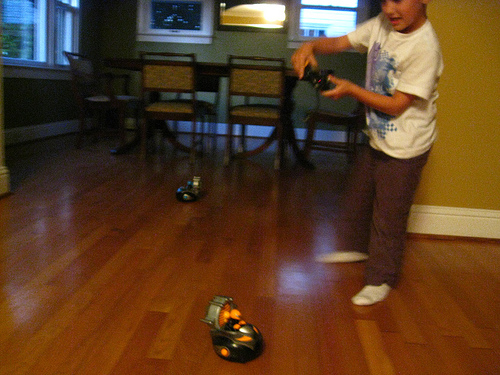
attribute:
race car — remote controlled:
[196, 290, 268, 365]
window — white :
[0, 4, 96, 79]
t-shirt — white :
[343, 7, 442, 158]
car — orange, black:
[199, 288, 268, 364]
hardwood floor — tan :
[3, 126, 495, 373]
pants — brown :
[330, 131, 444, 293]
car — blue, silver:
[177, 175, 207, 202]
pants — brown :
[352, 129, 436, 292]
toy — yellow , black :
[210, 292, 265, 361]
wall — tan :
[416, 7, 498, 213]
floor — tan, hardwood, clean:
[2, 124, 498, 371]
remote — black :
[298, 68, 332, 90]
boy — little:
[295, 2, 435, 307]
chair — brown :
[222, 53, 290, 165]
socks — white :
[350, 279, 394, 311]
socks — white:
[316, 250, 391, 305]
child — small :
[334, 11, 402, 244]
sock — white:
[348, 279, 388, 306]